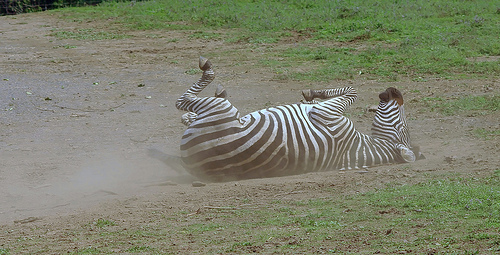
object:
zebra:
[157, 58, 426, 182]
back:
[195, 164, 373, 183]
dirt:
[1, 1, 498, 254]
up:
[0, 0, 497, 96]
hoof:
[198, 57, 213, 71]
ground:
[0, 2, 498, 254]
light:
[3, 3, 496, 253]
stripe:
[297, 106, 328, 171]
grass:
[114, 2, 498, 74]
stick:
[179, 205, 237, 218]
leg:
[305, 86, 360, 124]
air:
[0, 1, 500, 255]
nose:
[379, 89, 403, 105]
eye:
[400, 122, 406, 127]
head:
[371, 87, 423, 165]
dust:
[77, 130, 208, 197]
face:
[381, 90, 409, 138]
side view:
[177, 55, 424, 177]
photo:
[2, 3, 497, 254]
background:
[0, 3, 498, 108]